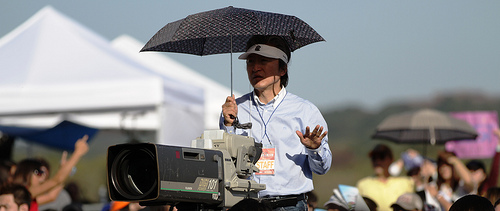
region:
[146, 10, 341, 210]
person holding an umbrella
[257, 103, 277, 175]
tag around peron's neck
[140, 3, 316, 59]
black umbrella in hand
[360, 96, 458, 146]
black umbrella in hand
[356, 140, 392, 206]
person in the crowd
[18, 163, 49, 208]
person in the crowd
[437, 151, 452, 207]
person in the crowd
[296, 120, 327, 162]
hand of the director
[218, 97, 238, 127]
hand of the director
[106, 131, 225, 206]
spot light in front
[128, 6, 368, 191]
Man holding an umbrella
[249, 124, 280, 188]
Man has a staff sign around neck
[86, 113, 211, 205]
Man taking a video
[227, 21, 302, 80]
He is wearing a visor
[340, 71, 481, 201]
Man holding an umbrella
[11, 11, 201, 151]
White tent over the people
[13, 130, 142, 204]
Woman pointing in the air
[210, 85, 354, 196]
Man is wearing a blue shirt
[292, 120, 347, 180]
Man has his hand outstretched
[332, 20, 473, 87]
The sky is blue no clouds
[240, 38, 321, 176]
this is a man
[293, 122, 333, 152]
the hand is raised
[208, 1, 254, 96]
he is carrying an umbrella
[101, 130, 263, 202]
this is a camera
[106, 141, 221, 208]
the camera is big in size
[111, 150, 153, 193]
the front is black in color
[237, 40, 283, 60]
he is wearing a cap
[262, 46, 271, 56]
the cap is white in color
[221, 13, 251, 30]
the umbrella is black in color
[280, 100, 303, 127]
the t shirt is blue in color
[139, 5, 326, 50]
man is holding black umbrella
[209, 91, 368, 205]
man is wearing blue collared shirt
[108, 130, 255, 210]
man is standing behind black camera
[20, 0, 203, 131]
white pointed roofs on tents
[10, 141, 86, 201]
woman is pointing upward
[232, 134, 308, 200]
man wears red and yellow staff badge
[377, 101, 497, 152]
grey umbrella is in background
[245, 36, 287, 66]
man is wearing white cap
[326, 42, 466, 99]
sky is blue and clear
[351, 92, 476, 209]
person under umbrella wears yellow shirt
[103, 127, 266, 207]
Large black and grey camera.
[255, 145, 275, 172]
Red, white and yellow staff badge.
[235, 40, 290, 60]
White sun visor worn by a man.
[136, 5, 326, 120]
Black umbrella held by the cameraman.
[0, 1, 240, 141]
Two white tents in background.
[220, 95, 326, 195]
Light blue shirt worn by a man.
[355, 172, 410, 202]
Light yellow shirt worn a man.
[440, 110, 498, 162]
A pink colored squared held in background.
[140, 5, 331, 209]
Man standing with his black umbrella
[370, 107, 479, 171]
Brown colored umbrella in background.